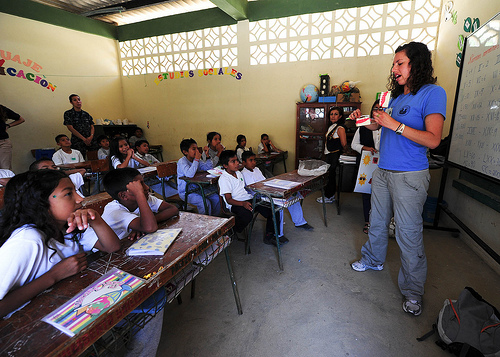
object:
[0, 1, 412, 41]
wall border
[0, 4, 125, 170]
wall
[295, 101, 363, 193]
cabinets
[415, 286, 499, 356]
backpack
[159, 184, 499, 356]
floor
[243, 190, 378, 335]
ground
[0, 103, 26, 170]
teacher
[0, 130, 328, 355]
class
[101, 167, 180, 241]
student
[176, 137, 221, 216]
student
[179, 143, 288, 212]
desk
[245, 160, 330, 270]
desk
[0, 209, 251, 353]
desk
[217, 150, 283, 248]
child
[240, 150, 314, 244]
child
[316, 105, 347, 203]
woman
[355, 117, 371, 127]
cards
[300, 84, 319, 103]
globe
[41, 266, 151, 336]
handbook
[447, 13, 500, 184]
board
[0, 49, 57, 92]
writing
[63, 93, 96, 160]
person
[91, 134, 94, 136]
bracelet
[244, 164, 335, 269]
desk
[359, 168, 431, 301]
pants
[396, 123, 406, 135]
watch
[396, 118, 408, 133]
wrist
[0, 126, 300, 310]
children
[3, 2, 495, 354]
classroom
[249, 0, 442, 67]
window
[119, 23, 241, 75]
window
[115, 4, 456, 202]
rear wall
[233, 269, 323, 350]
floor.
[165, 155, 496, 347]
flooring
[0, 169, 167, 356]
student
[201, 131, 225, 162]
student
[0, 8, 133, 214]
back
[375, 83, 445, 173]
shirt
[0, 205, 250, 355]
tables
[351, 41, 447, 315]
girl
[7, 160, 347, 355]
front row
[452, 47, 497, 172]
writing